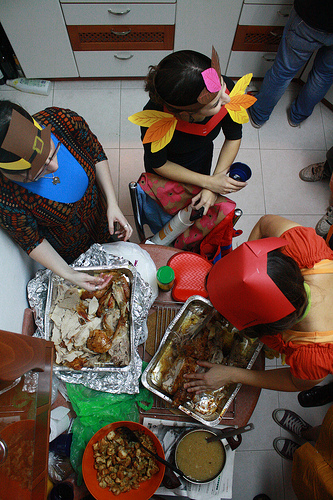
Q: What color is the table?
A: Brown.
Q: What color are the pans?
A: Silver.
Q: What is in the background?
A: Cabinets.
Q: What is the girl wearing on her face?
A: Glasses.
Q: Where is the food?
A: Table.